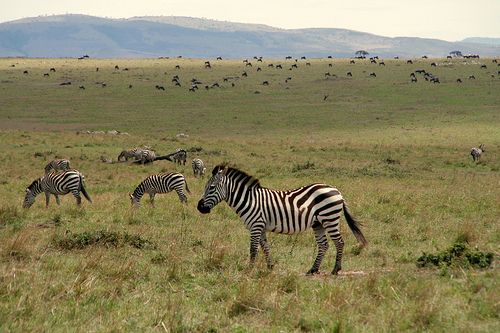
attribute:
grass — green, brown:
[1, 59, 498, 331]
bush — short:
[403, 228, 497, 290]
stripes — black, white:
[258, 176, 313, 216]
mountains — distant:
[2, 12, 497, 60]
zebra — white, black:
[198, 160, 373, 276]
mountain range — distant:
[3, 11, 498, 61]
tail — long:
[339, 188, 366, 246]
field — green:
[221, 97, 355, 157]